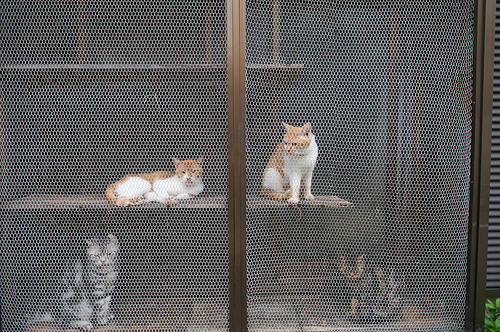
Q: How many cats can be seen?
A: 4.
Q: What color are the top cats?
A: Orange and white.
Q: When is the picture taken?
A: Daytime.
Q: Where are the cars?
A: In a cage.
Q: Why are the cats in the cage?
A: To keep them from getting away.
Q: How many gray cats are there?
A: 2.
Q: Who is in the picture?
A: No one.